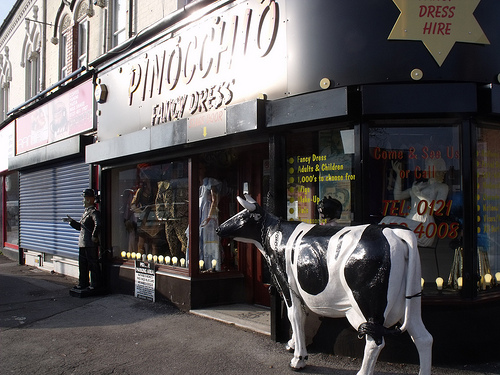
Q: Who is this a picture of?
A: Nobody.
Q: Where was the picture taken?
A: Storefront.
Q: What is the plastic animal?
A: Cow.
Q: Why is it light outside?
A: Sun.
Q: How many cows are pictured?
A: 1.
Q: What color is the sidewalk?
A: Grey.